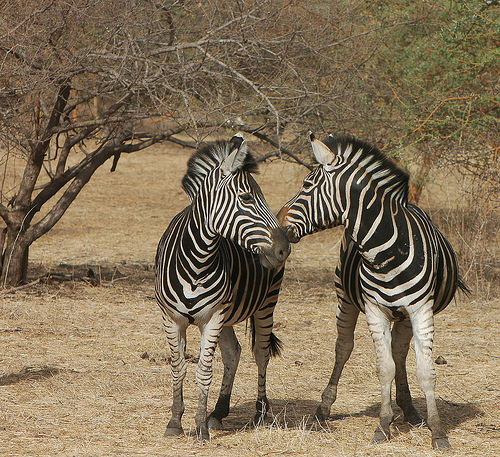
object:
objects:
[68, 258, 120, 287]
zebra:
[156, 135, 288, 444]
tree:
[4, 2, 154, 286]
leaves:
[419, 32, 480, 77]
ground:
[67, 169, 156, 456]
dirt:
[157, 380, 195, 439]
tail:
[245, 317, 283, 357]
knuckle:
[162, 352, 195, 384]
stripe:
[169, 242, 247, 314]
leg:
[165, 314, 188, 435]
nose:
[261, 238, 298, 270]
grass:
[7, 279, 169, 455]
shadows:
[220, 386, 339, 439]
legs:
[189, 318, 229, 451]